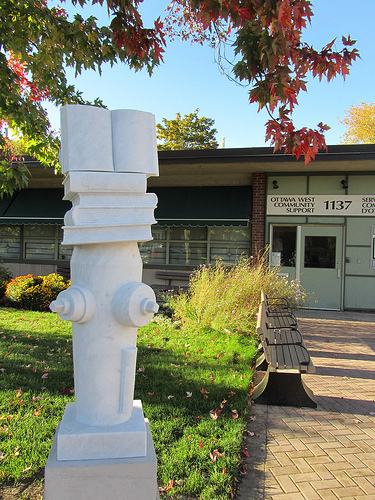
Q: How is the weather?
A: Sunny.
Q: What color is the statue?
A: White.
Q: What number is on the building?
A: 1137.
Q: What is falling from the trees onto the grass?
A: Leaves.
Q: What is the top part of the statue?
A: A book.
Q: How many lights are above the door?
A: 2.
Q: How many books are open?
A: One.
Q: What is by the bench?
A: Fall foliage.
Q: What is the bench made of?
A: Wood.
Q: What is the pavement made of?
A: Inlaid bricks.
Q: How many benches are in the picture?
A: Two.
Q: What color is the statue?
A: White.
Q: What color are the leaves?
A: Red and green.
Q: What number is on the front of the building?
A: 1137.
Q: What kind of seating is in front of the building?
A: Benches.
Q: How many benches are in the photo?
A: Four benches.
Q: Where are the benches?
A: On the walkway.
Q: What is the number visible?
A: 1137.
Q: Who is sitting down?
A: No one.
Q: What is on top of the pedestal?
A: A book.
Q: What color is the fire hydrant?
A: White.